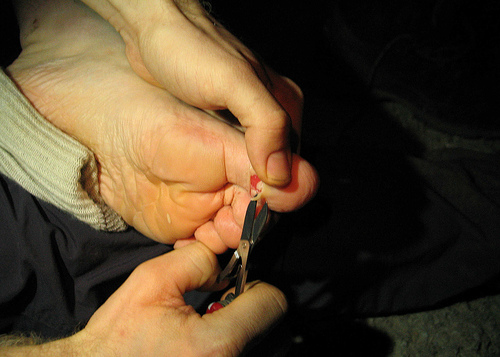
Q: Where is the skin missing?
A: Big toe of left foot.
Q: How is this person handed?
A: Right handed.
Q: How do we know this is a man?
A: Hairy arm.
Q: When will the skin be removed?
A: Now.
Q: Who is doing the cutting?
A: A man.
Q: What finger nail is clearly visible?
A: Left hand thumb.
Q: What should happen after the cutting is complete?
A: Area should be sanitized.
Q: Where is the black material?
A: On the ground.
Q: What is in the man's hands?
A: Scissors.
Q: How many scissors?
A: 1.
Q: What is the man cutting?
A: A toe.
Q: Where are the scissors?
A: His hands.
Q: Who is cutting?
A: A man.